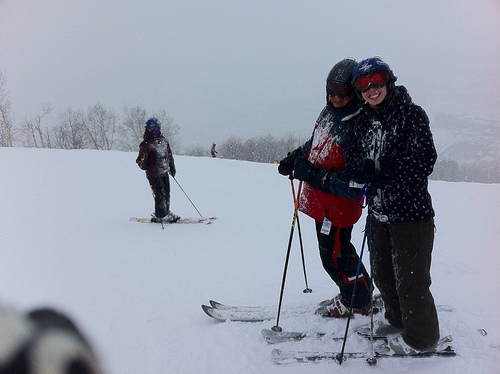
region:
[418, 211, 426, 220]
white dot on coat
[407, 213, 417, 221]
white dot on coat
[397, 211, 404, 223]
white dot on coat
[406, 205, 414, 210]
white dot on coat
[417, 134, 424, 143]
white dot on coat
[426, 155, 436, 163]
white dot on coat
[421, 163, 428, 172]
white dot on coat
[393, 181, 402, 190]
white dot on coat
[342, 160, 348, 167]
white dot on coat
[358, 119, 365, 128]
white dot on coat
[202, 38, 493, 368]
Two people standing beside each other on skis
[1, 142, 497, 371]
Snow covering the ground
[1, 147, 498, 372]
White thick snow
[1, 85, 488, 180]
Trees bare of all leaves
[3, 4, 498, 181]
A grey sky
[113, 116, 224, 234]
A person skiing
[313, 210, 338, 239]
A white ski lift pass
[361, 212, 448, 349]
Dark grey winter pants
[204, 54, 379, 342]
A woman holding a pair of ski poles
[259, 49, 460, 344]
Two people wearing winter goggles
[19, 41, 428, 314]
this is on a mountain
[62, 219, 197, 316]
the ground is covered in snow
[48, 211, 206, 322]
the ground is white in color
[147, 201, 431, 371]
these are skis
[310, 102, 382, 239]
the man has a black and red jacket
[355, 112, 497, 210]
this person has a white and black jacket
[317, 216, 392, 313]
the person's pants are blue and red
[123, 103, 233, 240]
skiier on the snow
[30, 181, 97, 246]
the snow is white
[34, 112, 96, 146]
snow on the trees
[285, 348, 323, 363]
snow on the skis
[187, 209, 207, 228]
snow on the skis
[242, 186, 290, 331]
ski pole on ground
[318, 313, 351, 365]
ski pole on ground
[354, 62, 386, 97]
blue and red hat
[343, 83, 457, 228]
black and white hoodie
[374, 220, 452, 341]
person has black pants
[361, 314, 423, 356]
black and grey shoes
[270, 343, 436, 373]
black and white skis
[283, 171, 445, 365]
person has black poles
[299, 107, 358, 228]
black and red shirt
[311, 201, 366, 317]
black and red pants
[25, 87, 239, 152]
bare trees in background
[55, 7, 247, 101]
grey and snowy sky